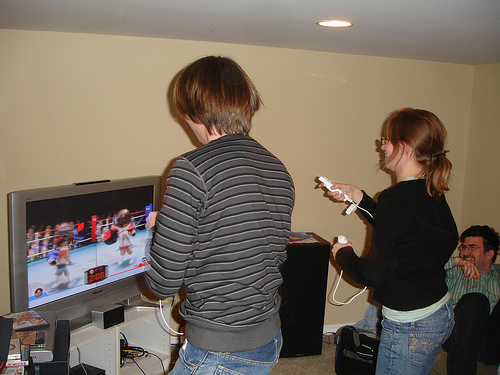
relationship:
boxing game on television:
[24, 185, 153, 314] [3, 169, 165, 326]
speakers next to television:
[281, 237, 325, 360] [10, 185, 165, 316]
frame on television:
[8, 195, 28, 312] [23, 201, 172, 297]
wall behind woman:
[1, 27, 497, 337] [314, 97, 483, 347]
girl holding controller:
[324, 108, 459, 373] [311, 167, 359, 214]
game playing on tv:
[28, 187, 164, 302] [3, 170, 168, 335]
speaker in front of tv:
[90, 304, 123, 329] [6, 174, 159, 319]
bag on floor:
[332, 325, 379, 374] [269, 334, 438, 373]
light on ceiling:
[311, 16, 355, 31] [1, 1, 498, 68]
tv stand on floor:
[55, 290, 187, 375] [269, 317, 499, 374]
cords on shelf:
[114, 334, 169, 372] [116, 315, 166, 368]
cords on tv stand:
[114, 334, 169, 372] [27, 305, 168, 374]